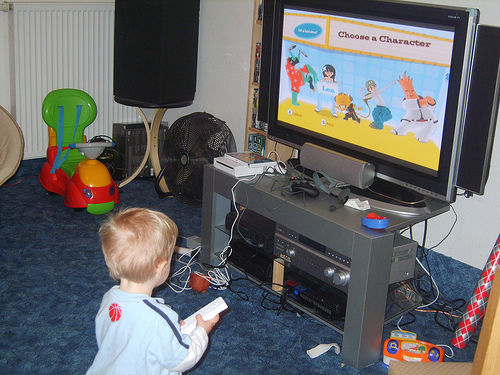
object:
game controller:
[181, 295, 229, 339]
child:
[71, 207, 221, 373]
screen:
[274, 10, 470, 178]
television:
[259, 0, 483, 217]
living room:
[4, 0, 500, 374]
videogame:
[382, 338, 446, 366]